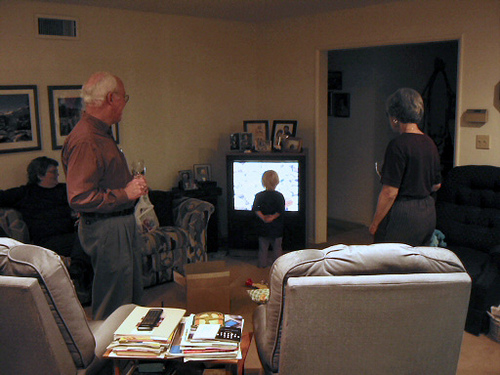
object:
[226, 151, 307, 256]
television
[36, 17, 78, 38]
vent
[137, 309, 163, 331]
remote control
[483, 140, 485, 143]
light switch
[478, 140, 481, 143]
light switch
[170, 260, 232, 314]
cardboard box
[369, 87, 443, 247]
woman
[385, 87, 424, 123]
hair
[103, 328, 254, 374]
table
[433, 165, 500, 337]
chair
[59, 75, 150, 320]
man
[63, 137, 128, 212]
arm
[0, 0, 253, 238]
wall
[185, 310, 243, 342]
books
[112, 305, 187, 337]
books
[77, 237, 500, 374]
floor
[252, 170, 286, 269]
boy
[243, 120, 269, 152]
pictures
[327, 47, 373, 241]
hallway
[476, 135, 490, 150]
switch panel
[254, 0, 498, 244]
wall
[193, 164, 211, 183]
pictures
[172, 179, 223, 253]
table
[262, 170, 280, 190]
hair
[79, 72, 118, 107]
hair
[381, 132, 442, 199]
shirt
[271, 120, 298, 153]
framed pictures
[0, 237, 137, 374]
chair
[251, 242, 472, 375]
chair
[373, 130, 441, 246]
outfit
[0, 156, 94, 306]
person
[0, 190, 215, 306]
couch